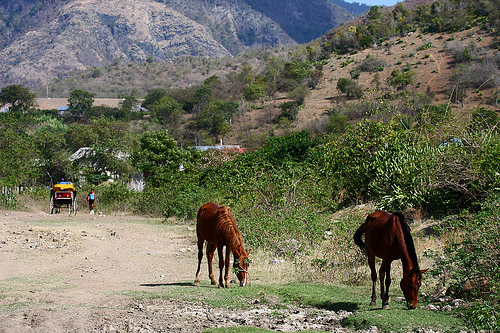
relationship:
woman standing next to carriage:
[87, 187, 95, 212] [49, 180, 78, 214]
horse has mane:
[195, 201, 255, 284] [218, 206, 248, 258]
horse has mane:
[353, 209, 429, 309] [393, 210, 421, 277]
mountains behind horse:
[0, 1, 376, 97] [195, 201, 255, 284]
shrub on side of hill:
[339, 79, 361, 101] [137, 0, 499, 311]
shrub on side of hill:
[387, 69, 413, 88] [137, 0, 499, 311]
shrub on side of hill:
[416, 42, 431, 52] [137, 0, 499, 311]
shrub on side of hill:
[329, 109, 347, 131] [137, 0, 499, 311]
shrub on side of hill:
[281, 101, 300, 118] [137, 0, 499, 311]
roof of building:
[1, 97, 149, 111] [0, 97, 151, 115]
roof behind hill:
[1, 97, 149, 111] [137, 0, 499, 311]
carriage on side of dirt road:
[49, 180, 78, 214] [2, 202, 283, 332]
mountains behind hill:
[0, 1, 376, 97] [137, 0, 499, 311]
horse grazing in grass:
[195, 201, 255, 284] [216, 281, 464, 332]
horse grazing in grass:
[353, 209, 429, 309] [216, 281, 464, 332]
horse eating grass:
[195, 201, 255, 284] [216, 281, 464, 332]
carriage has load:
[49, 180, 78, 214] [54, 184, 74, 191]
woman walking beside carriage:
[87, 187, 95, 212] [49, 180, 78, 214]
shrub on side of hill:
[358, 52, 385, 73] [137, 0, 499, 311]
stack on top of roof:
[219, 139, 224, 146] [187, 145, 239, 152]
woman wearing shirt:
[87, 187, 95, 212] [90, 193, 95, 200]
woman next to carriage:
[87, 187, 95, 212] [49, 180, 78, 214]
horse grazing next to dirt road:
[195, 201, 255, 284] [2, 202, 283, 332]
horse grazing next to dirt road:
[353, 209, 429, 309] [2, 202, 283, 332]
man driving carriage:
[59, 177, 66, 184] [49, 180, 78, 214]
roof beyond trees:
[1, 97, 149, 111] [4, 83, 168, 122]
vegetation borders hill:
[133, 118, 500, 312] [137, 0, 499, 311]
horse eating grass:
[353, 209, 429, 309] [216, 281, 464, 332]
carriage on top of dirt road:
[49, 180, 78, 214] [2, 202, 283, 332]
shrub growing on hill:
[278, 76, 299, 93] [137, 0, 499, 311]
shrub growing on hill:
[211, 110, 231, 135] [137, 0, 499, 311]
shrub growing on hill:
[422, 55, 429, 60] [137, 0, 499, 311]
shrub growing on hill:
[358, 52, 385, 73] [137, 0, 499, 311]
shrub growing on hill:
[329, 109, 347, 131] [137, 0, 499, 311]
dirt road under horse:
[2, 202, 283, 332] [195, 201, 255, 284]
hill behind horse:
[137, 0, 499, 311] [195, 201, 255, 284]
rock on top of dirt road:
[160, 273, 165, 278] [2, 202, 283, 332]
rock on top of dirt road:
[111, 231, 117, 238] [2, 202, 283, 332]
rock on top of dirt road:
[85, 256, 89, 260] [2, 202, 283, 332]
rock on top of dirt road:
[80, 273, 85, 280] [2, 202, 283, 332]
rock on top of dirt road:
[82, 233, 87, 239] [2, 202, 283, 332]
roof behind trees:
[1, 97, 149, 111] [4, 83, 168, 122]